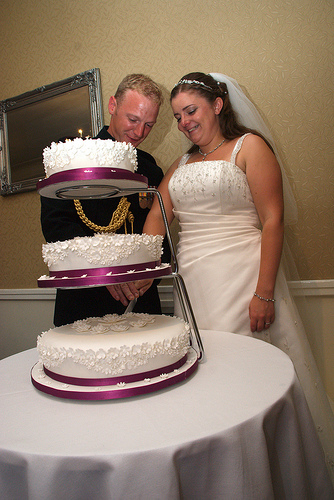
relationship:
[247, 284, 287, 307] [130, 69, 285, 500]
bracelet worn by lady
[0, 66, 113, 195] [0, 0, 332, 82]
mirror hangs on wall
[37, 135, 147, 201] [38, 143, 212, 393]
tier on cake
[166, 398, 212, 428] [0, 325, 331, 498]
table covered with linen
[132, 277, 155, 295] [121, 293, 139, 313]
hand holding knife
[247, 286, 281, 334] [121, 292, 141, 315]
hand holding knife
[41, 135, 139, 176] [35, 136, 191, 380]
frosting on cake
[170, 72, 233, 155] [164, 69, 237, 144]
head of lady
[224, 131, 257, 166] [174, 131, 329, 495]
strap of dress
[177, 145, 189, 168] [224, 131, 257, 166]
strap of strap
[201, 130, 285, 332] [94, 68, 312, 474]
arm of lady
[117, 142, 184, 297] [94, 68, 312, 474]
arm of lady